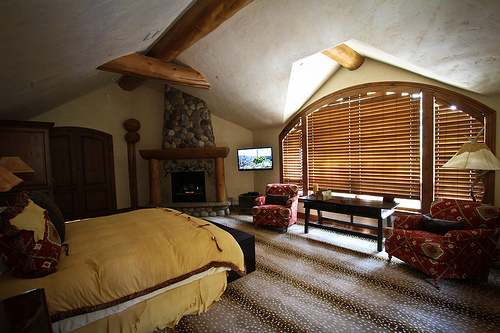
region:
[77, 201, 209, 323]
this is the bed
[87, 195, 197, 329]
the bed is well spread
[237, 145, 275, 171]
this is the screen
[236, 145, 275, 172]
the screen is on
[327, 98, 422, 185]
this is the window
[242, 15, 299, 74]
this is the ceiling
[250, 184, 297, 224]
this is the sofa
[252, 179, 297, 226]
the sofa is empty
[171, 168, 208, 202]
this is the fire place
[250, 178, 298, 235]
Red cushioned chair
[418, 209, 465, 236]
Rectangular brown leather pillow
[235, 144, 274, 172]
Flat wall mounted television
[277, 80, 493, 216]
Large bedroom window with wood blinds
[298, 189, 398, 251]
Dark brown wood coffee table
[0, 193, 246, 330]
Queen size bed with yellowish sheets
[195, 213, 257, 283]
Black rectangular chest at the end of the bed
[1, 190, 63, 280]
Decorative pattern red bed pillow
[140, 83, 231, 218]
Stone and wood fireplace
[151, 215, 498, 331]
Spotted area rug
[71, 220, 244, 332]
large tan bed cover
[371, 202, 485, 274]
red printed chair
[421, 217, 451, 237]
black pillow on the chair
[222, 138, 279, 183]
tv on the wall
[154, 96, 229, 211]
fireplace in the corner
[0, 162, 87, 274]
two pillows on the bed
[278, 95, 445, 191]
wooden blinds on the window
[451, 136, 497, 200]
white lamp behind chair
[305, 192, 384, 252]
dark coffee table between chair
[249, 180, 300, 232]
A red easy chair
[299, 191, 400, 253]
A dark wood coffee table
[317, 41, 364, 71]
A wood support beam in the ceiling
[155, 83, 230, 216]
A large stone fire place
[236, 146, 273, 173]
A TV mounted on the wall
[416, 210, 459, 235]
A dark pillow on the chair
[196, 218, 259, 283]
A black storage container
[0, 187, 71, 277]
Large pillows on the bed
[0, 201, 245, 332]
A very large bed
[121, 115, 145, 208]
A wood pole in the corner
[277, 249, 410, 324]
the floor is carpeted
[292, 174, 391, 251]
the table is wooden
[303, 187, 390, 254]
the table is black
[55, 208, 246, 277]
teh comforter is yellow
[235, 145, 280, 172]
the tv is on the wall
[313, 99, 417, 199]
the binds are wooden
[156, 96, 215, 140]
the chimney is made of rocks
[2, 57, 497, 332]
the scene is indoors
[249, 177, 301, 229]
the sofa is red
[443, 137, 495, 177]
the lampshade is brown